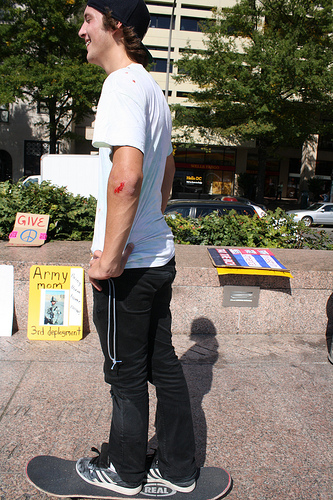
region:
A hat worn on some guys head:
[86, 0, 151, 29]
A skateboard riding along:
[24, 453, 231, 498]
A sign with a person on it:
[27, 265, 82, 340]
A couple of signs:
[206, 247, 293, 278]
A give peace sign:
[7, 212, 49, 247]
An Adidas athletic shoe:
[76, 456, 144, 494]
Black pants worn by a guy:
[91, 257, 200, 487]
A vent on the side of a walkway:
[223, 285, 258, 307]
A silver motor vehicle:
[286, 202, 331, 225]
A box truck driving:
[9, 154, 100, 196]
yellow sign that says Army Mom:
[28, 263, 82, 341]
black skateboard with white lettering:
[24, 453, 231, 497]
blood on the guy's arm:
[113, 183, 124, 192]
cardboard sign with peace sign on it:
[7, 211, 49, 246]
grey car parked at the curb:
[286, 199, 331, 226]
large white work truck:
[18, 154, 96, 197]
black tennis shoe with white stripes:
[76, 442, 143, 494]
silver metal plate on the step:
[221, 284, 259, 307]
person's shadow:
[144, 317, 218, 466]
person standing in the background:
[275, 181, 282, 198]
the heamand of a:
[64, 3, 163, 78]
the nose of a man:
[71, 23, 95, 49]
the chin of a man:
[78, 50, 111, 64]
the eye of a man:
[74, 8, 112, 28]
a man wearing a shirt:
[62, 48, 214, 287]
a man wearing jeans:
[55, 243, 213, 467]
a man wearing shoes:
[70, 395, 268, 494]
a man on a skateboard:
[37, 4, 240, 494]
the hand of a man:
[70, 234, 150, 312]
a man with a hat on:
[64, 0, 170, 71]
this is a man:
[72, 0, 186, 453]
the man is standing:
[68, 0, 180, 482]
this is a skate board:
[37, 463, 66, 485]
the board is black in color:
[44, 458, 66, 487]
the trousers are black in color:
[115, 294, 167, 457]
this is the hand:
[102, 155, 144, 255]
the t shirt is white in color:
[122, 82, 152, 111]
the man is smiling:
[81, 37, 97, 50]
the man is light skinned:
[99, 45, 117, 62]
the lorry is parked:
[64, 160, 96, 179]